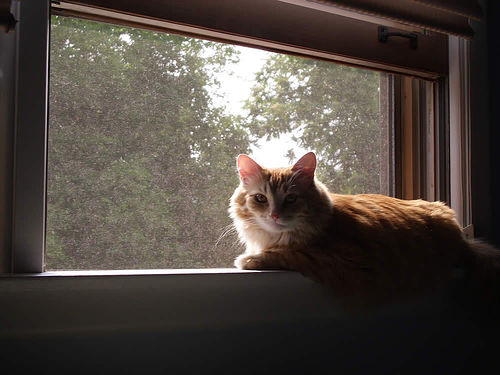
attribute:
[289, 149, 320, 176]
ear — pink, light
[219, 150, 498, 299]
cat — sitting, orange, white, laying, alert, looking, awake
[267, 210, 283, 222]
nose — pink, small, little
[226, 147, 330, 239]
head — furry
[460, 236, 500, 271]
tail — bushy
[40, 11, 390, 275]
trees — green, leafy, large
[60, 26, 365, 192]
sky — bright, blue, light, clear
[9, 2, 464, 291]
window — mesh, open, white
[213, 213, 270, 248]
whiskers — white